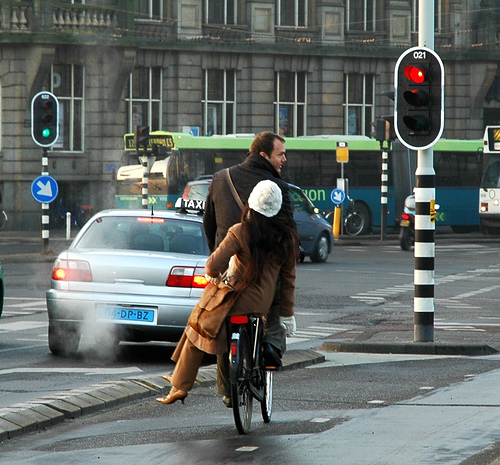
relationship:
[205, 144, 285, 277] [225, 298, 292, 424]
man on bike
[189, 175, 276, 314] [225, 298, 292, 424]
woman on bike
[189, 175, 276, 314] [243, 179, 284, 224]
woman wearing hat